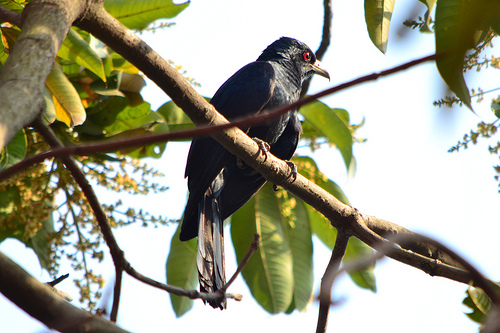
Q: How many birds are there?
A: One.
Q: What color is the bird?
A: Black.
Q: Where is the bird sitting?
A: On a branch.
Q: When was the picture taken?
A: Daytime.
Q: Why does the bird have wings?
A: So it can fly.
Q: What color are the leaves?
A: Green.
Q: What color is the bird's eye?
A: Red.